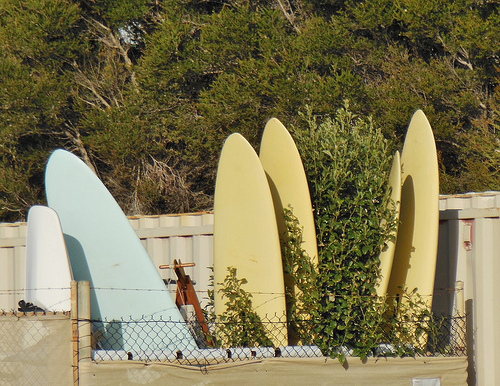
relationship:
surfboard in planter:
[45, 153, 196, 358] [70, 280, 472, 369]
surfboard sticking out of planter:
[19, 204, 74, 313] [70, 280, 472, 369]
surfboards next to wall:
[373, 97, 447, 344] [2, 169, 498, 347]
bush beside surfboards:
[297, 104, 387, 346] [215, 113, 318, 349]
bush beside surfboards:
[297, 104, 387, 346] [373, 97, 447, 344]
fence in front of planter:
[0, 283, 476, 378] [70, 280, 472, 369]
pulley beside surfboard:
[163, 257, 220, 356] [45, 153, 196, 358]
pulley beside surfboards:
[163, 257, 220, 356] [215, 113, 318, 349]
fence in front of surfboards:
[0, 283, 476, 378] [400, 102, 447, 344]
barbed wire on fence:
[3, 281, 497, 302] [0, 283, 476, 378]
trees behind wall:
[1, 4, 497, 203] [2, 169, 498, 347]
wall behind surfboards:
[2, 169, 498, 347] [400, 102, 447, 344]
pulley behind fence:
[163, 257, 220, 356] [0, 283, 476, 378]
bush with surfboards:
[297, 104, 387, 346] [400, 102, 447, 344]